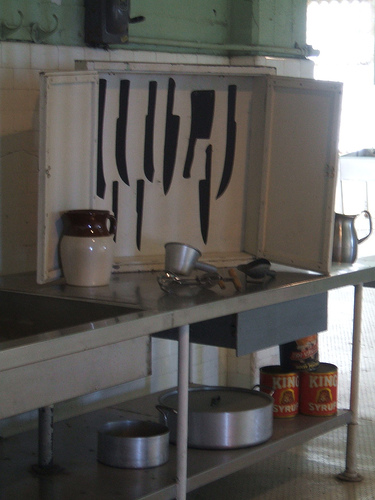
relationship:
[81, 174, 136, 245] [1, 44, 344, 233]
knife inside cabinet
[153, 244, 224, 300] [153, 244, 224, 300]
metal beaters in front of metal beaters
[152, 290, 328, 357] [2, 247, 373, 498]
drawer under table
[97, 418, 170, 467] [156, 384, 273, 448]
pan next to pot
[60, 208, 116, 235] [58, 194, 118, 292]
brown area on jar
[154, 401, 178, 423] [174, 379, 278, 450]
handle on pot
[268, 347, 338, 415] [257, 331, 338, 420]
labels on labels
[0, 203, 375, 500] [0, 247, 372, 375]
metal on countertop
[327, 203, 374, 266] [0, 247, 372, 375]
metal on countertop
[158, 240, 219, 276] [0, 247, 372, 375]
metal on countertop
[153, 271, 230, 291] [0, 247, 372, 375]
metal on countertop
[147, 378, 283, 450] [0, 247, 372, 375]
metal on countertop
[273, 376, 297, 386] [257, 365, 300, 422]
word king on can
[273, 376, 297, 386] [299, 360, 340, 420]
word king on can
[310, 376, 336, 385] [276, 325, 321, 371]
word king on can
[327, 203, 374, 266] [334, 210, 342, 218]
metal has spout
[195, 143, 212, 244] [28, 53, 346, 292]
knife in box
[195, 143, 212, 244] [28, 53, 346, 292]
knife has box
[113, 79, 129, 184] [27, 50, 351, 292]
knife in cabinet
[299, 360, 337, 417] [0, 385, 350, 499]
can on shelf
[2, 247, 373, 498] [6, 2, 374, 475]
table inside of kitchen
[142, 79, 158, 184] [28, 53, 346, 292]
knife in box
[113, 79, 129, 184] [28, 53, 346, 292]
knife in box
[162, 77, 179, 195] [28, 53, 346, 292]
knife in box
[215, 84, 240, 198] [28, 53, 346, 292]
knife in box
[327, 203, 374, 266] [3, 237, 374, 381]
metal on table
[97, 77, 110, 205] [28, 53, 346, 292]
knife in box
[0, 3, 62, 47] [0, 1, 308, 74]
hooks attached to wall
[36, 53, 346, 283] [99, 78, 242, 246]
box holding knives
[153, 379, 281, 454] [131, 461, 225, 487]
pot sitting on shelf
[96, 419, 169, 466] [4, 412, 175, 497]
stock pot on shelf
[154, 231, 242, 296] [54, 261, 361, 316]
pot on shelf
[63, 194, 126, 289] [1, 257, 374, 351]
jar on counter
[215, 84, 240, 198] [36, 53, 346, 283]
knife in box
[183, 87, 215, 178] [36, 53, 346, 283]
knife in box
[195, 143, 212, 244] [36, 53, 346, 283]
knife in box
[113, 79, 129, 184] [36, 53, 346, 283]
knife in box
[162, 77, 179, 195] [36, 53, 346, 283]
knife in box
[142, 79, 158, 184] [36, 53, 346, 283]
knife in box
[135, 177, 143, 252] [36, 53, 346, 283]
knife in box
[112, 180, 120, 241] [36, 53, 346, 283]
knife in box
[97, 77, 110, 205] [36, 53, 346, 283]
knife in box